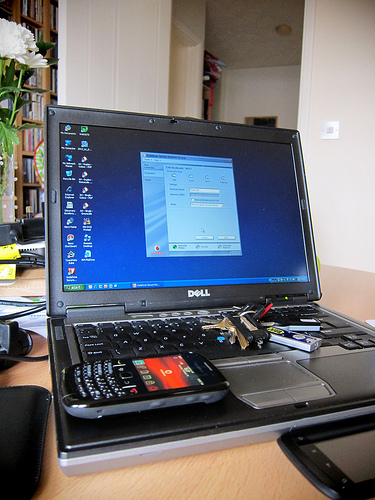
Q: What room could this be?
A: It is an office.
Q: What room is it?
A: It is an office.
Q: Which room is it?
A: It is an office.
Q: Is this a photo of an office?
A: Yes, it is showing an office.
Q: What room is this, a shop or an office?
A: It is an office.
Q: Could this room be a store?
A: No, it is an office.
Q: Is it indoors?
A: Yes, it is indoors.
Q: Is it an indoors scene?
A: Yes, it is indoors.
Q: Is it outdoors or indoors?
A: It is indoors.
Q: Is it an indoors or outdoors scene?
A: It is indoors.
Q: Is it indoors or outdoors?
A: It is indoors.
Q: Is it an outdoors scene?
A: No, it is indoors.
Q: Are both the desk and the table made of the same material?
A: Yes, both the desk and the table are made of wood.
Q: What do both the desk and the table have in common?
A: The material, both the desk and the table are wooden.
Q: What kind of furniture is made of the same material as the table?
A: The desk is made of the same material as the table.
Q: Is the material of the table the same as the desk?
A: Yes, both the table and the desk are made of wood.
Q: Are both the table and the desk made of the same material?
A: Yes, both the table and the desk are made of wood.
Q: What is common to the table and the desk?
A: The material, both the table and the desk are wooden.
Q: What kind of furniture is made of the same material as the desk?
A: The table is made of the same material as the desk.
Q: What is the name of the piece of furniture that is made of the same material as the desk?
A: The piece of furniture is a table.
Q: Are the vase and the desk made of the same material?
A: No, the vase is made of glass and the desk is made of wood.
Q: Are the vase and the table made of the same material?
A: No, the vase is made of glass and the table is made of wood.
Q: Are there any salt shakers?
A: No, there are no salt shakers.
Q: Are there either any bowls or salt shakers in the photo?
A: No, there are no salt shakers or bowls.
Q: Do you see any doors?
A: Yes, there is a door.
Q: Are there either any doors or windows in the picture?
A: Yes, there is a door.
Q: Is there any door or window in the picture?
A: Yes, there is a door.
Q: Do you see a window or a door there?
A: Yes, there is a door.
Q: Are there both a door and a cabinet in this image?
A: No, there is a door but no cabinets.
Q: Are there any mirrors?
A: No, there are no mirrors.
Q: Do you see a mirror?
A: No, there are no mirrors.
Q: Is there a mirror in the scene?
A: No, there are no mirrors.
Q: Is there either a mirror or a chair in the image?
A: No, there are no mirrors or chairs.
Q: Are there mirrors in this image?
A: No, there are no mirrors.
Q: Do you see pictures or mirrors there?
A: No, there are no mirrors or pictures.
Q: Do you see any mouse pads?
A: No, there are no mouse pads.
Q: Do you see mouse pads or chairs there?
A: No, there are no mouse pads or chairs.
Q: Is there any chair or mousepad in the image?
A: No, there are no mouse pads or chairs.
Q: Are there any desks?
A: Yes, there is a desk.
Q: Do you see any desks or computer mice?
A: Yes, there is a desk.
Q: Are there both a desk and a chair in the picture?
A: No, there is a desk but no chairs.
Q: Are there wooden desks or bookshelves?
A: Yes, there is a wood desk.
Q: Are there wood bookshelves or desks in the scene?
A: Yes, there is a wood desk.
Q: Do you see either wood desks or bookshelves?
A: Yes, there is a wood desk.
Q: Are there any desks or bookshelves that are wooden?
A: Yes, the desk is wooden.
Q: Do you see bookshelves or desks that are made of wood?
A: Yes, the desk is made of wood.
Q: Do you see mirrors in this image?
A: No, there are no mirrors.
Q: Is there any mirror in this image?
A: No, there are no mirrors.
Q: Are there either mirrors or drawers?
A: No, there are no mirrors or drawers.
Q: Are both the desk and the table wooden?
A: Yes, both the desk and the table are wooden.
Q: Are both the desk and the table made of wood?
A: Yes, both the desk and the table are made of wood.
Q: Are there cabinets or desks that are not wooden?
A: No, there is a desk but it is wooden.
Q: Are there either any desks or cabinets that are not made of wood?
A: No, there is a desk but it is made of wood.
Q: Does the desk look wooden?
A: Yes, the desk is wooden.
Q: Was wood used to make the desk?
A: Yes, the desk is made of wood.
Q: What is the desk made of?
A: The desk is made of wood.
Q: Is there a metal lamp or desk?
A: No, there is a desk but it is wooden.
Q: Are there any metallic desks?
A: No, there is a desk but it is wooden.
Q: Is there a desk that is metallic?
A: No, there is a desk but it is wooden.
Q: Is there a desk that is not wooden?
A: No, there is a desk but it is wooden.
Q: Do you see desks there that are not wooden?
A: No, there is a desk but it is wooden.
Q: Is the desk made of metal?
A: No, the desk is made of wood.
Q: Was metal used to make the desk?
A: No, the desk is made of wood.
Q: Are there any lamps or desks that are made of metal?
A: No, there is a desk but it is made of wood.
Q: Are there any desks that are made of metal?
A: No, there is a desk but it is made of wood.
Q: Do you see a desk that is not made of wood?
A: No, there is a desk but it is made of wood.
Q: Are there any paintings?
A: No, there are no paintings.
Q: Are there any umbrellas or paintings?
A: No, there are no paintings or umbrellas.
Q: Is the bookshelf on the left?
A: Yes, the bookshelf is on the left of the image.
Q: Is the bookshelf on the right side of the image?
A: No, the bookshelf is on the left of the image.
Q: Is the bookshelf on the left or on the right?
A: The bookshelf is on the left of the image.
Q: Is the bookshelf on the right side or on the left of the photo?
A: The bookshelf is on the left of the image.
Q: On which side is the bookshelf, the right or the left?
A: The bookshelf is on the left of the image.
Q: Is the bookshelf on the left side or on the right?
A: The bookshelf is on the left of the image.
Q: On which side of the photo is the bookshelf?
A: The bookshelf is on the left of the image.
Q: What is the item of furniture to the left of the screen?
A: The piece of furniture is a bookshelf.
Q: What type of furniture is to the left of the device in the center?
A: The piece of furniture is a bookshelf.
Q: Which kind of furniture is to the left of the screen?
A: The piece of furniture is a bookshelf.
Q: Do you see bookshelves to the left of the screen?
A: Yes, there is a bookshelf to the left of the screen.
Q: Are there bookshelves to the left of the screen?
A: Yes, there is a bookshelf to the left of the screen.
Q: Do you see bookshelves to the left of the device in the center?
A: Yes, there is a bookshelf to the left of the screen.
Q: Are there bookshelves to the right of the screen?
A: No, the bookshelf is to the left of the screen.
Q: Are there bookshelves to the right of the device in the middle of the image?
A: No, the bookshelf is to the left of the screen.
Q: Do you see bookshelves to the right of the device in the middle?
A: No, the bookshelf is to the left of the screen.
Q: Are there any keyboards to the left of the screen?
A: No, there is a bookshelf to the left of the screen.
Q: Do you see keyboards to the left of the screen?
A: No, there is a bookshelf to the left of the screen.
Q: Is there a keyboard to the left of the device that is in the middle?
A: No, there is a bookshelf to the left of the screen.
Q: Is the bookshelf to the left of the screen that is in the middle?
A: Yes, the bookshelf is to the left of the screen.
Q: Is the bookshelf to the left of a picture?
A: No, the bookshelf is to the left of the screen.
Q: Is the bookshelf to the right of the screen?
A: No, the bookshelf is to the left of the screen.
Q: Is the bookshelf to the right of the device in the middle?
A: No, the bookshelf is to the left of the screen.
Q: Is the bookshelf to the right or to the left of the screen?
A: The bookshelf is to the left of the screen.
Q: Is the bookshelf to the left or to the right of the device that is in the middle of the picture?
A: The bookshelf is to the left of the screen.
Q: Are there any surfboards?
A: No, there are no surfboards.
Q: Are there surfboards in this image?
A: No, there are no surfboards.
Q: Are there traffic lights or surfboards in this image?
A: No, there are no surfboards or traffic lights.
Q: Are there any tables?
A: Yes, there is a table.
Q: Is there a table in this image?
A: Yes, there is a table.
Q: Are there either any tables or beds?
A: Yes, there is a table.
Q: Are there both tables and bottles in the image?
A: No, there is a table but no bottles.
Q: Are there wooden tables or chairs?
A: Yes, there is a wood table.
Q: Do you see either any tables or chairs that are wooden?
A: Yes, the table is wooden.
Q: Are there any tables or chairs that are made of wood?
A: Yes, the table is made of wood.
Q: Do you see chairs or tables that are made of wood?
A: Yes, the table is made of wood.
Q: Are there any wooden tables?
A: Yes, there is a wood table.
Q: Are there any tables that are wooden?
A: Yes, there is a table that is wooden.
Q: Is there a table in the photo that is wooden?
A: Yes, there is a table that is wooden.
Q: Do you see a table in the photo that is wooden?
A: Yes, there is a table that is wooden.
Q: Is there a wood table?
A: Yes, there is a table that is made of wood.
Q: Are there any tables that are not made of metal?
A: Yes, there is a table that is made of wood.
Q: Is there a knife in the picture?
A: No, there are no knives.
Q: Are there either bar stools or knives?
A: No, there are no knives or bar stools.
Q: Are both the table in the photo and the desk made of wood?
A: Yes, both the table and the desk are made of wood.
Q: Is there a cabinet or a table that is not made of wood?
A: No, there is a table but it is made of wood.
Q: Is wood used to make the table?
A: Yes, the table is made of wood.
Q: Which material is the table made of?
A: The table is made of wood.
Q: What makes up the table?
A: The table is made of wood.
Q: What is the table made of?
A: The table is made of wood.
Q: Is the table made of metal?
A: No, the table is made of wood.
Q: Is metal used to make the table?
A: No, the table is made of wood.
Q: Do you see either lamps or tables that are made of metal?
A: No, there is a table but it is made of wood.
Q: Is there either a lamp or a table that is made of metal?
A: No, there is a table but it is made of wood.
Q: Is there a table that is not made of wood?
A: No, there is a table but it is made of wood.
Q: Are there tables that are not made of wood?
A: No, there is a table but it is made of wood.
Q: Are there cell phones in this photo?
A: Yes, there is a cell phone.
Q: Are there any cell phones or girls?
A: Yes, there is a cell phone.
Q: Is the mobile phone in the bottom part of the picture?
A: Yes, the mobile phone is in the bottom of the image.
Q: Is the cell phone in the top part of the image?
A: No, the cell phone is in the bottom of the image.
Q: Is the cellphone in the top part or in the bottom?
A: The cellphone is in the bottom of the image.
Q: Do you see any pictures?
A: No, there are no pictures.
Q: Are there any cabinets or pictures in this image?
A: No, there are no pictures or cabinets.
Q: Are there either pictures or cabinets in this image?
A: No, there are no pictures or cabinets.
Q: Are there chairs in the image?
A: No, there are no chairs.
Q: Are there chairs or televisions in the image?
A: No, there are no chairs or televisions.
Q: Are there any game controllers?
A: No, there are no game controllers.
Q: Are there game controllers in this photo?
A: No, there are no game controllers.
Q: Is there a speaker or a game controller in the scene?
A: No, there are no game controllers or speakers.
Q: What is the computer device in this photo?
A: The device is a screen.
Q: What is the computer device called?
A: The device is a screen.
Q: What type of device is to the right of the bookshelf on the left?
A: The device is a screen.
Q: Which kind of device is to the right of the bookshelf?
A: The device is a screen.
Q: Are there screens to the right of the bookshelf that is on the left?
A: Yes, there is a screen to the right of the bookshelf.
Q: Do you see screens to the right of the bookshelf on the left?
A: Yes, there is a screen to the right of the bookshelf.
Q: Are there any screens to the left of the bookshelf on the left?
A: No, the screen is to the right of the bookshelf.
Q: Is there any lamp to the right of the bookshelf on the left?
A: No, there is a screen to the right of the bookshelf.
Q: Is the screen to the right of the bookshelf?
A: Yes, the screen is to the right of the bookshelf.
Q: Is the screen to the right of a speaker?
A: No, the screen is to the right of the bookshelf.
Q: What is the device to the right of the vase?
A: The device is a screen.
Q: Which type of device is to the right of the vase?
A: The device is a screen.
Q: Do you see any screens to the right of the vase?
A: Yes, there is a screen to the right of the vase.